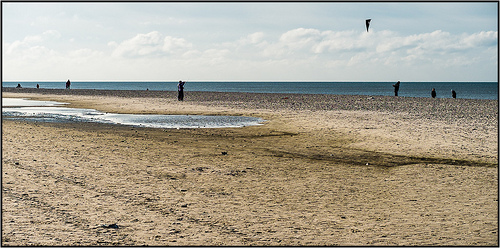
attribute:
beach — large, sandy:
[3, 88, 495, 243]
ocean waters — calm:
[2, 83, 497, 98]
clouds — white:
[2, 5, 496, 84]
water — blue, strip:
[6, 76, 496, 100]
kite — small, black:
[364, 14, 374, 31]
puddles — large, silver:
[7, 93, 269, 133]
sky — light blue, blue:
[2, 2, 499, 80]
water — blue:
[6, 78, 499, 102]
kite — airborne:
[364, 14, 373, 34]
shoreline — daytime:
[3, 84, 495, 109]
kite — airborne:
[365, 15, 374, 34]